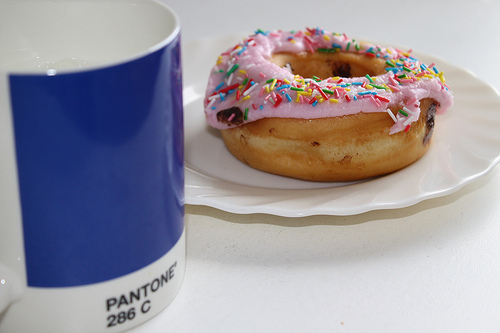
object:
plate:
[180, 52, 500, 219]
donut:
[202, 25, 454, 183]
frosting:
[202, 26, 452, 136]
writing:
[104, 259, 177, 327]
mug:
[0, 0, 188, 333]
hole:
[269, 48, 391, 81]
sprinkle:
[242, 82, 258, 96]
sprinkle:
[285, 93, 292, 101]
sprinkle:
[386, 108, 397, 123]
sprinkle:
[296, 88, 312, 96]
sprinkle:
[244, 107, 249, 120]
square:
[8, 29, 181, 288]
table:
[120, 0, 499, 332]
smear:
[216, 106, 244, 126]